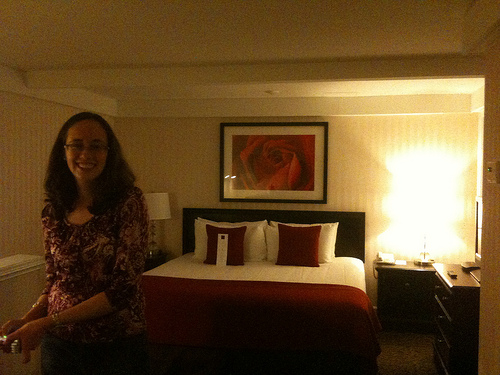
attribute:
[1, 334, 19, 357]
camera — silver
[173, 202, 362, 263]
headboard — black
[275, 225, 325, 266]
throw pillow — red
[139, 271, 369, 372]
blanket — red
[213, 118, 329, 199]
rose photo — framed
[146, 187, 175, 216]
lamp shade — white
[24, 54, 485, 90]
beam — white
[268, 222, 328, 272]
pillow — red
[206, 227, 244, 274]
pillow — red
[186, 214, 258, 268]
pillow — white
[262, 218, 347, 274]
pillow — white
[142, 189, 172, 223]
lamp shade — white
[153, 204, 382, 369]
bed — queen sized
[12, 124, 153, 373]
woman — pregnant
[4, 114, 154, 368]
woman — brown haired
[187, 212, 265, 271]
pillows — rust, cream, decorative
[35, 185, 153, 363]
dress — long, floral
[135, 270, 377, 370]
comforter — rust color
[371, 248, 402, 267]
telephone — white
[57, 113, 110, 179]
face — smiling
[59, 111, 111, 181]
face — laughing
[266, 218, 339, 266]
pillows — rust, cream, decorative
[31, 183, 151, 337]
shirt — printed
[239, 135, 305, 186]
rose — red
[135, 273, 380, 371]
bed covering — red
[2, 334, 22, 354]
item — white